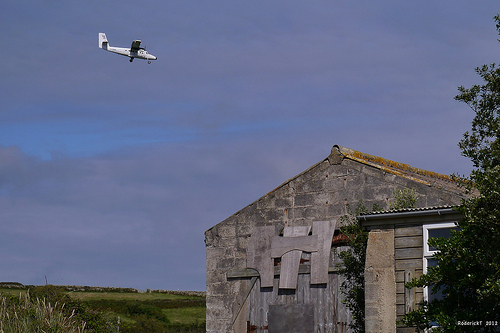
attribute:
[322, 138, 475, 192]
moss — orange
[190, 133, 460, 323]
grey stone — front of building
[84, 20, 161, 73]
aeroplane — white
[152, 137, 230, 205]
cloud — white in the blue sky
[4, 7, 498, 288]
clouds — white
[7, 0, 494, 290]
sky — blue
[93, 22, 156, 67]
plane — white, small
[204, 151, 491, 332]
farm building — old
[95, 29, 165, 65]
plane — small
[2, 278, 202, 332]
fields — green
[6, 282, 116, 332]
plant — tall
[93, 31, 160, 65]
plane — small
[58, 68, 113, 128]
clouds — white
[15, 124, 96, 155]
sky — blue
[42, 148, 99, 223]
sky — blue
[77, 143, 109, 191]
clouds — white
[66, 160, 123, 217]
clouds — white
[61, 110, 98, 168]
sky — blue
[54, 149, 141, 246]
clouds — white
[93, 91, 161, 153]
sky — blue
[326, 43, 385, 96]
sky — blue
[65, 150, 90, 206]
clouds — white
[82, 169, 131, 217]
clouds — white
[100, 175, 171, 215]
sky — blue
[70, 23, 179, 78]
plane — white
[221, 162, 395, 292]
building — white, brown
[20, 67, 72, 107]
clouds — white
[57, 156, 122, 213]
sky — blue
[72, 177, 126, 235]
clouds — white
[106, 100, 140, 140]
sky — blue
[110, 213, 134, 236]
sky — blue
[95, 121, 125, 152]
clouds — white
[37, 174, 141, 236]
clouds — white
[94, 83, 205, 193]
sky — blue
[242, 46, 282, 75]
sky — blue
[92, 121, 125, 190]
clouds — white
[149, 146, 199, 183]
clouds — white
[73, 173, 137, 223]
sky — blue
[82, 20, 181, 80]
airplane — white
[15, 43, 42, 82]
clouds — white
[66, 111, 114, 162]
sky — blue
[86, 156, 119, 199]
sky — blue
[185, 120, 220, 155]
clouds — white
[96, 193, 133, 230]
clouds — white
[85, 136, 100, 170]
sky — blue